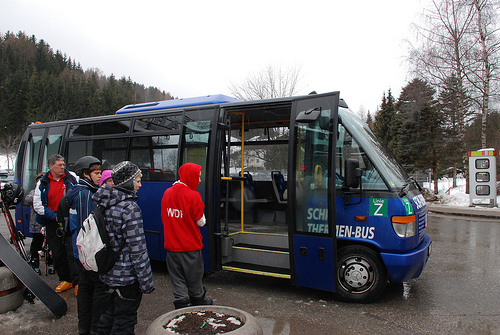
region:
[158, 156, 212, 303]
Man wearing a red hoodie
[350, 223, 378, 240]
White letters spelling bus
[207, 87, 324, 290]
Open passenger loading door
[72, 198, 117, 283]
White backpack on person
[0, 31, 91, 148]
Hill covered in trees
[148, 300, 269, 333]
Round cigarette disposing can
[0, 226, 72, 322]
Snowboard leaning against a pot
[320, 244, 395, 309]
Black bus wheel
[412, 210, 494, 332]
Road slick from snow and rain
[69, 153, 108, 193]
Young man wearing a helmet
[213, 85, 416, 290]
blue bus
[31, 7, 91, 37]
white clouds in blue sky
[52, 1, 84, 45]
white clouds in blue sky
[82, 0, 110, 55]
white clouds in blue sky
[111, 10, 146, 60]
white clouds in blue sky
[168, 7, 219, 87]
white clouds in blue sky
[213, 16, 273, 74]
white clouds in blue sky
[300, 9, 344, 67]
white clouds in blue sky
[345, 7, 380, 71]
white clouds in blue sky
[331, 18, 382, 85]
white clouds in blue sky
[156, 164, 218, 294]
person wearing red jacket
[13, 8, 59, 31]
white clouds in blue sky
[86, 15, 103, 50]
white clouds in blue sky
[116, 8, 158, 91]
white clouds in blue sky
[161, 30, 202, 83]
white clouds in blue sky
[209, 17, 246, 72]
white clouds in blue sky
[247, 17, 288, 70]
white clouds in blue sky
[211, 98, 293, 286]
open door on the bus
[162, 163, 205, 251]
reddish orange hoodie on man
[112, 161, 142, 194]
hat on a woman's head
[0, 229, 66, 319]
a snow board leaning on something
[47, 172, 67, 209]
red shirt on a man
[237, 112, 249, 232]
yellow pole inside the bus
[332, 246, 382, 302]
front tire on the bus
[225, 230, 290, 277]
steps to the bus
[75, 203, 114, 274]
black and white backpack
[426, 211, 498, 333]
moisture on the streets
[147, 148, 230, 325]
this is a man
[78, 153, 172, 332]
this is a man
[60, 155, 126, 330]
this is a man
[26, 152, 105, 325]
this is a man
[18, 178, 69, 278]
this is a man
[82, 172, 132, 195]
this is a man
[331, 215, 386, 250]
a name of the bus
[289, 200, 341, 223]
a name of the bus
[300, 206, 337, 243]
a name of the bus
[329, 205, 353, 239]
a name of the bus